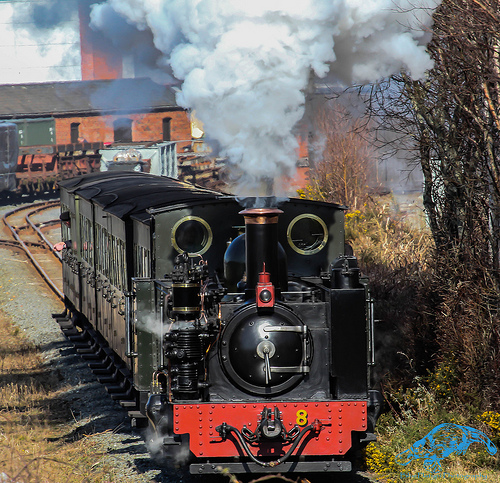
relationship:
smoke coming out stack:
[6, 0, 444, 207] [238, 207, 281, 294]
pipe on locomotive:
[238, 207, 284, 302] [52, 170, 381, 475]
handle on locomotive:
[363, 294, 382, 369] [52, 170, 381, 475]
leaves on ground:
[365, 442, 399, 478] [378, 393, 434, 443]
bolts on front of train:
[172, 400, 215, 420] [124, 197, 355, 396]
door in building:
[111, 116, 133, 141] [2, 73, 202, 180]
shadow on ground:
[15, 324, 152, 476] [24, 308, 121, 430]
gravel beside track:
[56, 350, 120, 423] [8, 186, 88, 292]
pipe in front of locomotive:
[233, 195, 304, 302] [52, 170, 381, 475]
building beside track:
[1, 73, 342, 196] [2, 202, 62, 286]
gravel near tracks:
[2, 276, 74, 346] [6, 202, 59, 287]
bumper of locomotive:
[170, 396, 371, 467] [66, 181, 271, 425]